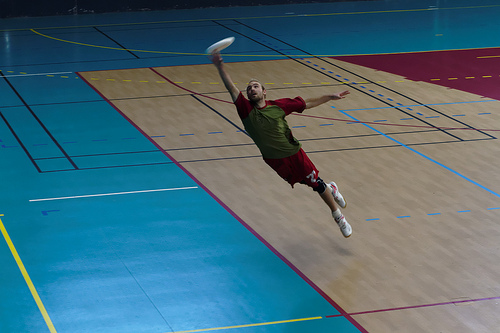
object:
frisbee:
[204, 36, 236, 56]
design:
[306, 170, 322, 184]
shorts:
[265, 148, 320, 189]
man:
[209, 49, 353, 238]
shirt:
[233, 90, 305, 160]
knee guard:
[311, 176, 327, 193]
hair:
[248, 78, 258, 82]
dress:
[232, 90, 319, 189]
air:
[164, 12, 262, 32]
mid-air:
[207, 48, 353, 239]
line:
[28, 185, 198, 201]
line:
[0, 215, 57, 332]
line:
[335, 109, 498, 196]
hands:
[207, 48, 226, 70]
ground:
[0, 0, 499, 331]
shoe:
[332, 213, 354, 239]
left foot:
[333, 214, 353, 238]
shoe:
[327, 179, 348, 208]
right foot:
[323, 181, 347, 209]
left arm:
[282, 94, 332, 109]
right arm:
[216, 65, 248, 114]